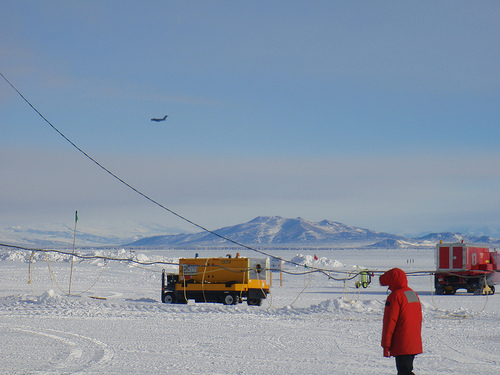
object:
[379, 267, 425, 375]
man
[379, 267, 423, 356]
coat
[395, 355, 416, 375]
pants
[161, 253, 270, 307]
truck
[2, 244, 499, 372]
snow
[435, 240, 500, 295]
truck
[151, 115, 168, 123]
airplane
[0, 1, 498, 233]
sky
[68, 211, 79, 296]
pole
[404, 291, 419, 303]
patch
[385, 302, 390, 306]
patch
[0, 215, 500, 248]
mountain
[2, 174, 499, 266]
background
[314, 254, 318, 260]
flag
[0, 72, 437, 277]
cord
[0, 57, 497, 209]
clouds